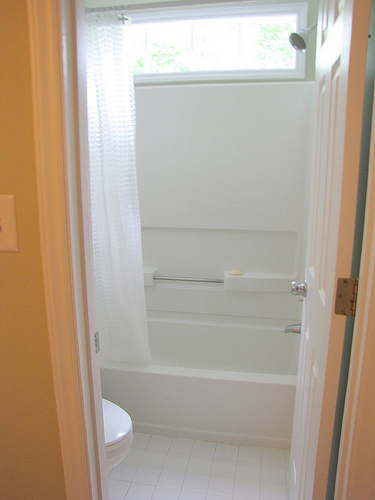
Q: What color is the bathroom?
A: White.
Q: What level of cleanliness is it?
A: Very clean.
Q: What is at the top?
A: Window.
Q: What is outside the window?
A: Trees.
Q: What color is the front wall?
A: Peach.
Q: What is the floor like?
A: Tiled.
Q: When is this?
A: Afternoon.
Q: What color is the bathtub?
A: White.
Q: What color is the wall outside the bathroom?
A: Orange.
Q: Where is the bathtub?
A: In the bathroom.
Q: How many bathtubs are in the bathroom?
A: One.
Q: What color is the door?
A: White.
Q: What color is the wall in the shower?
A: White.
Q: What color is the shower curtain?
A: White.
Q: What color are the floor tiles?
A: White.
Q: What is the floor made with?
A: Tiles.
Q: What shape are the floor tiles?
A: Square.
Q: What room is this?
A: Bathroom.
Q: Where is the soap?
A: Shelf on back wall.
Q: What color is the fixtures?
A: Silver.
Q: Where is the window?
A: Top.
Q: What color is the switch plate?
A: White.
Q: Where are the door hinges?
A: On right.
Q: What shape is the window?
A: Rectangle.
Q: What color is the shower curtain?
A: Clear.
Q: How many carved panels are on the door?
A: 6.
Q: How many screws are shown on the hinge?
A: 3.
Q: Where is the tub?
A: Next to the toilet.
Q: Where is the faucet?
A: Above the tub.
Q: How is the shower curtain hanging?
A: Down and open.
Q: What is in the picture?
A: A bathroom.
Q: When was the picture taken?
A: Daytime.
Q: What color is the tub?
A: White.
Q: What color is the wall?
A: Brown.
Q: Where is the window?
A: Above the tub.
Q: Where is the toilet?
A: On the wall.